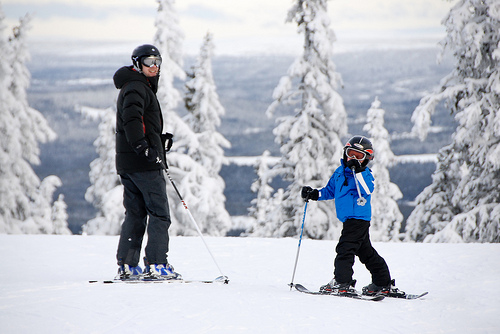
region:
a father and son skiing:
[99, 28, 460, 317]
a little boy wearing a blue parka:
[289, 62, 474, 330]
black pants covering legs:
[342, 224, 390, 285]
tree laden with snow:
[417, 9, 494, 239]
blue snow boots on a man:
[121, 258, 170, 279]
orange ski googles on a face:
[344, 146, 367, 166]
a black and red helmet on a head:
[348, 137, 380, 154]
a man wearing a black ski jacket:
[111, 40, 208, 300]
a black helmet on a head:
[126, 42, 166, 63]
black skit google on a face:
[144, 56, 166, 66]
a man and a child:
[110, 41, 398, 305]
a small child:
[293, 132, 398, 302]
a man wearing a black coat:
[110, 43, 189, 288]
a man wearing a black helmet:
[110, 42, 187, 286]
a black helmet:
[129, 40, 164, 65]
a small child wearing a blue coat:
[296, 132, 403, 301]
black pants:
[333, 220, 389, 284]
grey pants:
[116, 171, 172, 261]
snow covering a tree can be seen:
[265, 1, 350, 130]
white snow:
[2, 285, 247, 332]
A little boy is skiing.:
[262, 124, 427, 304]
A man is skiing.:
[79, 39, 243, 301]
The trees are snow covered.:
[160, 30, 334, 218]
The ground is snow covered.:
[109, 290, 311, 332]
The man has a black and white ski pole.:
[144, 147, 239, 299]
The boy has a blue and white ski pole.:
[286, 192, 326, 309]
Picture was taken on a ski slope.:
[1, 5, 493, 332]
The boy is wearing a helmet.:
[323, 131, 380, 168]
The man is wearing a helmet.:
[111, 39, 176, 74]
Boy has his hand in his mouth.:
[300, 137, 380, 192]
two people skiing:
[53, 5, 492, 328]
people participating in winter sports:
[100, 22, 440, 332]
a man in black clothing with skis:
[62, 25, 299, 327]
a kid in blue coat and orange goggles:
[278, 91, 480, 301]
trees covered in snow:
[80, 32, 499, 326]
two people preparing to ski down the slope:
[76, 9, 492, 332]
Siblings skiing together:
[38, 11, 477, 302]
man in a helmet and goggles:
[71, 18, 236, 265]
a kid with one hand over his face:
[233, 41, 474, 332]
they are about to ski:
[51, 22, 415, 332]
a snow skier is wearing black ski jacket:
[113, 43, 180, 282]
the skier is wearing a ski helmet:
[131, 44, 161, 72]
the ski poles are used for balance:
[152, 146, 229, 283]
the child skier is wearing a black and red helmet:
[345, 135, 375, 163]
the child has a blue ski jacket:
[317, 163, 374, 222]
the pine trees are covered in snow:
[1, 9, 67, 235]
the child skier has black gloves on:
[301, 186, 318, 200]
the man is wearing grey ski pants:
[116, 172, 171, 262]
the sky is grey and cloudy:
[1, 1, 498, 53]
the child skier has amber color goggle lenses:
[343, 145, 374, 162]